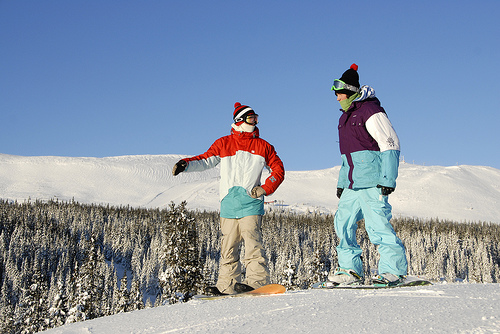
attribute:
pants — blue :
[338, 196, 433, 271]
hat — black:
[326, 61, 362, 87]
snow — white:
[130, 240, 151, 255]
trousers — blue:
[333, 187, 409, 275]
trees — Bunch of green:
[3, 195, 499, 331]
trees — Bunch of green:
[44, 205, 146, 260]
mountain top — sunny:
[3, 132, 352, 277]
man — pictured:
[179, 85, 301, 307]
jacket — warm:
[322, 107, 461, 198]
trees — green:
[6, 194, 206, 332]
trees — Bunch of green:
[10, 173, 156, 332]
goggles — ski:
[231, 113, 276, 129]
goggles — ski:
[326, 79, 360, 92]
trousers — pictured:
[216, 217, 269, 283]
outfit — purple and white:
[340, 102, 378, 225]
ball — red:
[114, 148, 207, 197]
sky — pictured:
[3, 0, 499, 169]